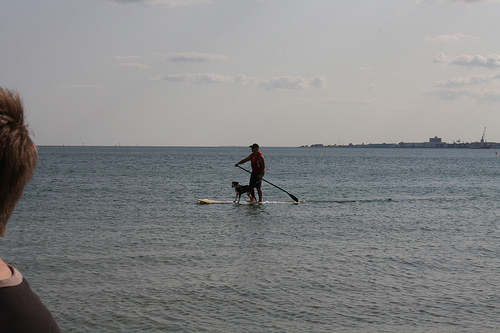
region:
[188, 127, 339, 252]
This is a person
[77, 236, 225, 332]
Section of a lake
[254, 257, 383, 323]
Section of a lake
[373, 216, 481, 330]
Section of a lake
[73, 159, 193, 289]
Section of a lake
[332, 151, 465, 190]
Section of a lake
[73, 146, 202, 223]
Section of a lake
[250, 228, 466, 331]
Section of a lake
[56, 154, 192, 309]
Section of a lake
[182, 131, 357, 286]
a person paddling in the water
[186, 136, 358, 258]
a man on a paddleboard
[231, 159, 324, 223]
a paddle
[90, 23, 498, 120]
clouds in the sky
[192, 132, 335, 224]
a man in a red shirt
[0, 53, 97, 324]
the edge of a man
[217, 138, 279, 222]
dog on paddleboard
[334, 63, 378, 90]
white clouds in blue sky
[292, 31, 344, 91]
white clouds in blue sky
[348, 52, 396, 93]
white clouds in blue sky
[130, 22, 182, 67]
white clouds in blue sky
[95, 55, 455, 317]
A person is standing on something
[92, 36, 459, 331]
A dog is standing with his master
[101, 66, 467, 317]
A person is using a paddle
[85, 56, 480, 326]
A person is close to the beach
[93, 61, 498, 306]
A person is close to a city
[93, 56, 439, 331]
A person is getting some exercise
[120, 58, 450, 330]
A person is having some recreation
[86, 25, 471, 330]
A person is having a great time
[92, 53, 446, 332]
A person is enjoying their day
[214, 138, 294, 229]
person and dog on paddleboard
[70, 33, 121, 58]
white clouds in blue sky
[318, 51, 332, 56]
white clouds in blue sky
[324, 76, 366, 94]
white clouds in blue sky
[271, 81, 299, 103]
white clouds in blue sky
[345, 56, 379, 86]
white clouds in blue sky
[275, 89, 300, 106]
white clouds in blue sky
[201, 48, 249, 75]
white clouds in blue sky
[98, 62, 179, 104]
white clouds in blue sky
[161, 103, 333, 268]
a man on a paddle board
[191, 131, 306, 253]
a dog on a paddle board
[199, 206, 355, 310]
a body of water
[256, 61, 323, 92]
a white fluffy cloud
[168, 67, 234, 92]
a white fluffy cloud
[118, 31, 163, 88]
a white fluffy cloud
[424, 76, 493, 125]
a white fluffy cloud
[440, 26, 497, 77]
a white fluffy cloud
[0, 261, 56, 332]
the shoulder of a person wearing a black shirt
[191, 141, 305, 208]
A man on a paddleboard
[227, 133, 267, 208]
A man with his dog on the board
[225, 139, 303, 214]
a Man paddling in the water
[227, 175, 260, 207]
A dog standing on a paddleboard